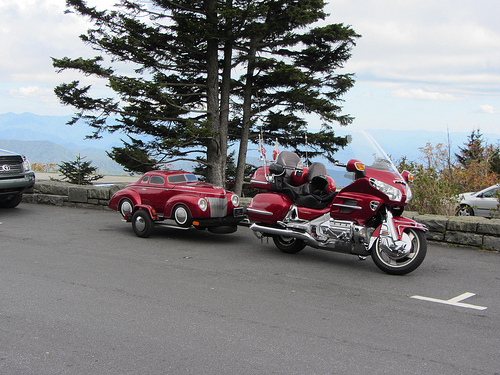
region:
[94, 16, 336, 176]
green and wide tree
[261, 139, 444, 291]
red cycle on road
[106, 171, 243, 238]
tiny red car behind cycle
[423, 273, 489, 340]
white lines on road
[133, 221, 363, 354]
road is dark grey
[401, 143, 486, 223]
green and orange trees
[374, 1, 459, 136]
white and blue sky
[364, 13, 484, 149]
layers of clouds in sky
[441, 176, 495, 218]
white car behind bike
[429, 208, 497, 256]
stone guard fence behind bike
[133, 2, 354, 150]
Tall green tree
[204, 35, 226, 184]
Main trunk of tree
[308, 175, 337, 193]
red helmet placed on bike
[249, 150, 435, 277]
red color bike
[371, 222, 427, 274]
Front wheel of the bike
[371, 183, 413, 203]
Head light of the bike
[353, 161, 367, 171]
Indicator of bike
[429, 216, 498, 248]
wall made of stone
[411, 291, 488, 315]
White mark on road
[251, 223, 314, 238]
Silencer of the bike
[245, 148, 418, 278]
red motorcycle parked on street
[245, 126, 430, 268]
cherry red motorcycle parked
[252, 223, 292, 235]
silver exhaust of motorcycle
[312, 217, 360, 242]
silver engine of motorcycle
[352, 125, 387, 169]
front windshield of motorcycle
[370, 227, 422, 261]
front black wheel of motorcycle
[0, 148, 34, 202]
front end of parked car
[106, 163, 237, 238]
small red car on trailer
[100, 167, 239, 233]
miniature red car on trailer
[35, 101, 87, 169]
mountain range in background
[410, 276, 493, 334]
white lines painted in the road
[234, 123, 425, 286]
red motorcycle in the street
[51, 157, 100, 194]
bush on side of road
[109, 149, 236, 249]
small car attached to bike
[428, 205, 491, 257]
stone fence along side of road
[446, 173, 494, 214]
silver car on opposite road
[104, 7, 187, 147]
green leaves of a tree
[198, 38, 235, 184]
trunk of a tree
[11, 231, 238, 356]
black paved street where bike is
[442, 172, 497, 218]
A car off of the road.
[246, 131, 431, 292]
A red motorcycle with a U.S. flag on the back.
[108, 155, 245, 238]
A red car model being towed.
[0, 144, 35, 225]
The front-end of a 4-runner.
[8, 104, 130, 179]
Mountains in the background.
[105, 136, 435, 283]
A red motorcycle pulling a red model car.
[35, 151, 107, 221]
A tree behind a stone wall.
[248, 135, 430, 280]
A motorcycle parker in the road.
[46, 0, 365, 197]
A big tree next to the road.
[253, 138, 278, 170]
The United States flag.